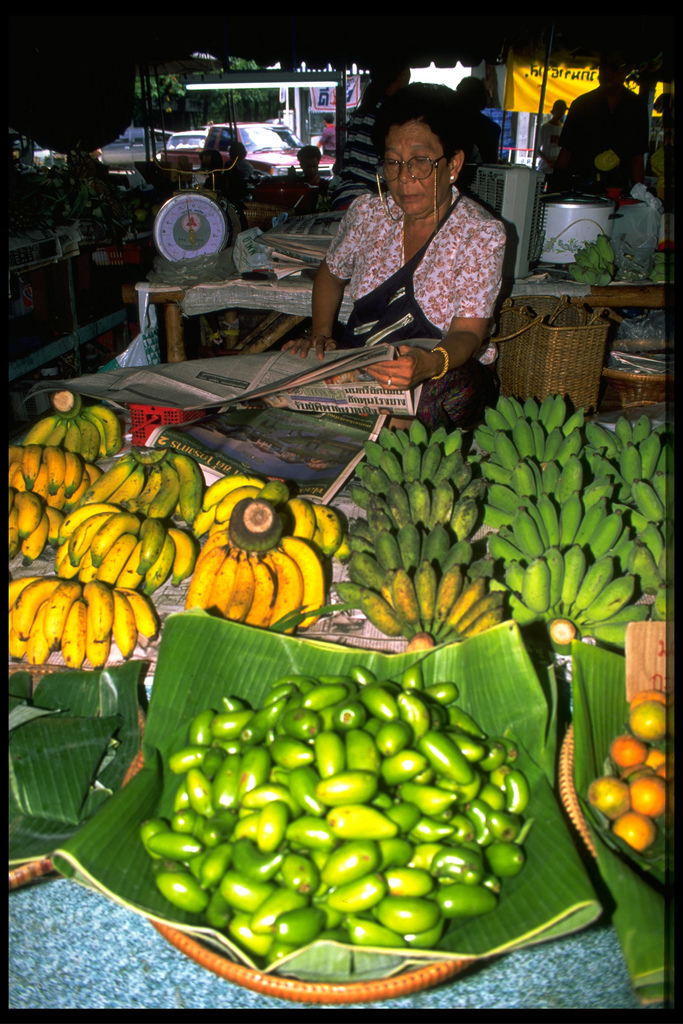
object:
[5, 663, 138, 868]
basket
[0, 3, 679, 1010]
building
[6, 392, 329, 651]
cluster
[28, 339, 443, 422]
newspaper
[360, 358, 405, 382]
finger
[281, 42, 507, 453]
woman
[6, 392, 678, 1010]
womantable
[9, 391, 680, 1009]
table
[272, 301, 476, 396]
hands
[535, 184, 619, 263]
crock pot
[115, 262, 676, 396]
shelf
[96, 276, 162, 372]
bag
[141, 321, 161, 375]
design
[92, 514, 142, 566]
banana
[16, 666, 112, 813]
leaves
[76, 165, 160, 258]
wall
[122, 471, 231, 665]
bananas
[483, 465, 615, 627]
bananas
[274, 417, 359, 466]
picture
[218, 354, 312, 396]
tag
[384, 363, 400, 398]
ring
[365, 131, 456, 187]
glasses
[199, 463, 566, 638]
bananas